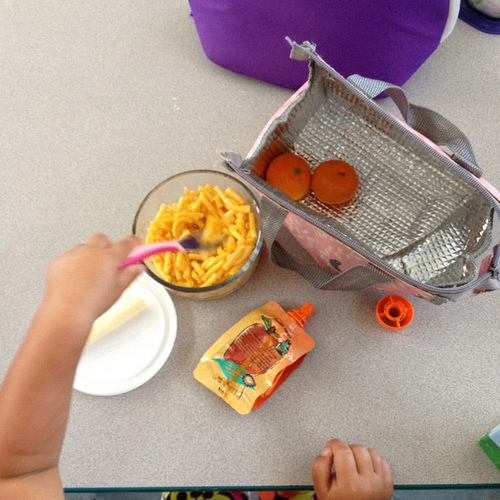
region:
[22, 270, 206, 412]
the plate is white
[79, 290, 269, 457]
the plate is white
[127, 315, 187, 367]
the plate is white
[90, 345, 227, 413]
the plate is white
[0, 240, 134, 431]
that is the hand of a child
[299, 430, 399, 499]
that is the hand of a child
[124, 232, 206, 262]
the child is holding a spoon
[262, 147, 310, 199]
that is an orange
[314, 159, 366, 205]
that is an orange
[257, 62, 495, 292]
that is a picnic pack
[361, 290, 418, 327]
that is the sachet's cap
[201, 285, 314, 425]
that is a sachet of snacks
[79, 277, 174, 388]
that's an empty plate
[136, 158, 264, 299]
there are snacks in the bowl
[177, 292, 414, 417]
orange pouch with lid off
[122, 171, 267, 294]
Mac and cheese in a bowl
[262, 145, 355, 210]
two oranges inside cooler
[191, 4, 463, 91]
purple cooler pail on table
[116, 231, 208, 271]
pink and white fork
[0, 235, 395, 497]
persons hands above table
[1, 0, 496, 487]
table is flecked gray and white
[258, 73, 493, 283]
silver inside of tote back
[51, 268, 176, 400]
white container lid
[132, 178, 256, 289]
mac and cheese is orange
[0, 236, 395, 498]
person is sitting at table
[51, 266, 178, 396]
white lid for mac and cheese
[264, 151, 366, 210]
two oranges in tote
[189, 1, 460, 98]
purple and white cooler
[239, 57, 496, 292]
inside of bag is silver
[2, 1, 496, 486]
table is white and gray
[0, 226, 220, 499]
person is holding fork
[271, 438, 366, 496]
a hand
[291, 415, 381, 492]
a hand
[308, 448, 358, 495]
a hand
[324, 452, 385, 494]
a hand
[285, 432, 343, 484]
a hand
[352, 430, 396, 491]
a hand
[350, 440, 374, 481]
a hand